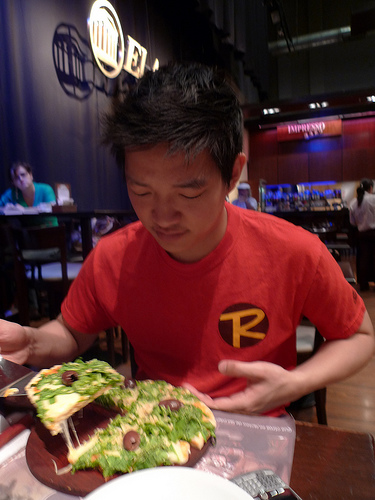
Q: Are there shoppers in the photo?
A: No, there are no shoppers.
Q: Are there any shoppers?
A: No, there are no shoppers.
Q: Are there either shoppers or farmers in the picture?
A: No, there are no shoppers or farmers.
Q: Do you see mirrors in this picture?
A: No, there are no mirrors.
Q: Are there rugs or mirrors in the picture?
A: No, there are no mirrors or rugs.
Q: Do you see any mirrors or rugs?
A: No, there are no mirrors or rugs.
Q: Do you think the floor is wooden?
A: Yes, the floor is wooden.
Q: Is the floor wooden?
A: Yes, the floor is wooden.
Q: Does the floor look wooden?
A: Yes, the floor is wooden.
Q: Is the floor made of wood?
A: Yes, the floor is made of wood.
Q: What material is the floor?
A: The floor is made of wood.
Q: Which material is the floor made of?
A: The floor is made of wood.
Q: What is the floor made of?
A: The floor is made of wood.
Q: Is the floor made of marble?
A: No, the floor is made of wood.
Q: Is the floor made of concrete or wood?
A: The floor is made of wood.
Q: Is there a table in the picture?
A: Yes, there is a table.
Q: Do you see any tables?
A: Yes, there is a table.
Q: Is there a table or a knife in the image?
A: Yes, there is a table.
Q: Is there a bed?
A: No, there are no beds.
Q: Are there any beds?
A: No, there are no beds.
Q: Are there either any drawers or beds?
A: No, there are no beds or drawers.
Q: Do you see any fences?
A: No, there are no fences.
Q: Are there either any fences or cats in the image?
A: No, there are no fences or cats.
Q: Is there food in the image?
A: Yes, there is food.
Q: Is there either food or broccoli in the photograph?
A: Yes, there is food.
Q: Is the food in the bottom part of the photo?
A: Yes, the food is in the bottom of the image.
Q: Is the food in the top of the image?
A: No, the food is in the bottom of the image.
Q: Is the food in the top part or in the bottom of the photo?
A: The food is in the bottom of the image.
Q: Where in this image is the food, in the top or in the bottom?
A: The food is in the bottom of the image.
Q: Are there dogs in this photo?
A: No, there are no dogs.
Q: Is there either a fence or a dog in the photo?
A: No, there are no dogs or fences.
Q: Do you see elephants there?
A: No, there are no elephants.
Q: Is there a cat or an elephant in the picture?
A: No, there are no elephants or cats.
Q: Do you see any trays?
A: No, there are no trays.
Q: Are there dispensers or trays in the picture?
A: No, there are no trays or dispensers.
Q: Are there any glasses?
A: No, there are no glasses.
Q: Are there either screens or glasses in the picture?
A: No, there are no glasses or screens.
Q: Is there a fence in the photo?
A: No, there are no fences.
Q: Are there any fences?
A: No, there are no fences.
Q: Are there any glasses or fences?
A: No, there are no fences or glasses.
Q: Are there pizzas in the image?
A: Yes, there is a pizza.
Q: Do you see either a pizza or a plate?
A: Yes, there is a pizza.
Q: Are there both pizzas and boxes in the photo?
A: No, there is a pizza but no boxes.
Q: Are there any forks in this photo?
A: No, there are no forks.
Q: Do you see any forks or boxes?
A: No, there are no forks or boxes.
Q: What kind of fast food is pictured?
A: The fast food is a pizza.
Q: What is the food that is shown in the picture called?
A: The food is a pizza.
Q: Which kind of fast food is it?
A: The food is a pizza.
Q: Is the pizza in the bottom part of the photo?
A: Yes, the pizza is in the bottom of the image.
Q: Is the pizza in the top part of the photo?
A: No, the pizza is in the bottom of the image.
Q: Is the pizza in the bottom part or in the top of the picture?
A: The pizza is in the bottom of the image.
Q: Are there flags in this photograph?
A: No, there are no flags.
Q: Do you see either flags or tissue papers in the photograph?
A: No, there are no flags or tissue papers.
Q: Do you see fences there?
A: No, there are no fences.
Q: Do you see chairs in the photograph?
A: Yes, there is a chair.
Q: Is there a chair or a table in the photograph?
A: Yes, there is a chair.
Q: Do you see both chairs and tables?
A: Yes, there are both a chair and a table.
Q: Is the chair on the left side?
A: Yes, the chair is on the left of the image.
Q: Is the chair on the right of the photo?
A: No, the chair is on the left of the image.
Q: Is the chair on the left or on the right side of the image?
A: The chair is on the left of the image.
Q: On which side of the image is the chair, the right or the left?
A: The chair is on the left of the image.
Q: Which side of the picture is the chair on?
A: The chair is on the left of the image.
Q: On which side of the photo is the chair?
A: The chair is on the left of the image.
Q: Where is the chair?
A: The chair is at the table.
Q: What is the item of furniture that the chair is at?
A: The piece of furniture is a table.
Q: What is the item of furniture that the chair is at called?
A: The piece of furniture is a table.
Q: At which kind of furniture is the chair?
A: The chair is at the table.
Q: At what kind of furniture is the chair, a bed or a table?
A: The chair is at a table.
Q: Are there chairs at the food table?
A: Yes, there is a chair at the table.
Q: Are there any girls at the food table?
A: No, there is a chair at the table.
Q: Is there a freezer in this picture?
A: No, there are no refrigerators.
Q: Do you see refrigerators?
A: No, there are no refrigerators.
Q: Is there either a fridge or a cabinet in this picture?
A: No, there are no refrigerators or cabinets.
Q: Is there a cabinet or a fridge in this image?
A: No, there are no refrigerators or cabinets.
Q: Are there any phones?
A: Yes, there is a phone.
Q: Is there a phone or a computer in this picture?
A: Yes, there is a phone.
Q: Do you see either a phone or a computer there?
A: Yes, there is a phone.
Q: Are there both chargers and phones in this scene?
A: No, there is a phone but no chargers.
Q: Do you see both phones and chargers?
A: No, there is a phone but no chargers.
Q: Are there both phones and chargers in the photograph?
A: No, there is a phone but no chargers.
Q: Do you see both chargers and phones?
A: No, there is a phone but no chargers.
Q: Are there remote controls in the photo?
A: No, there are no remote controls.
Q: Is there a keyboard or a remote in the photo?
A: No, there are no remote controls or keyboards.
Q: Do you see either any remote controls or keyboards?
A: No, there are no remote controls or keyboards.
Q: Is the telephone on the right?
A: Yes, the telephone is on the right of the image.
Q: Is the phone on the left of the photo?
A: No, the phone is on the right of the image.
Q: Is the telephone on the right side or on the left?
A: The telephone is on the right of the image.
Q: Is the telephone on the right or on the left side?
A: The telephone is on the right of the image.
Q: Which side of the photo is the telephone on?
A: The telephone is on the right of the image.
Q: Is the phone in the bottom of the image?
A: Yes, the phone is in the bottom of the image.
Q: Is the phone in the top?
A: No, the phone is in the bottom of the image.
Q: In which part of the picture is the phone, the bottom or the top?
A: The phone is in the bottom of the image.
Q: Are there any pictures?
A: No, there are no pictures.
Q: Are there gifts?
A: No, there are no gifts.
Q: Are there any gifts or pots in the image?
A: No, there are no gifts or pots.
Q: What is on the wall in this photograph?
A: The letter is on the wall.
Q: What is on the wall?
A: The letter is on the wall.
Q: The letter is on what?
A: The letter is on the wall.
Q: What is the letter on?
A: The letter is on the wall.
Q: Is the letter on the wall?
A: Yes, the letter is on the wall.